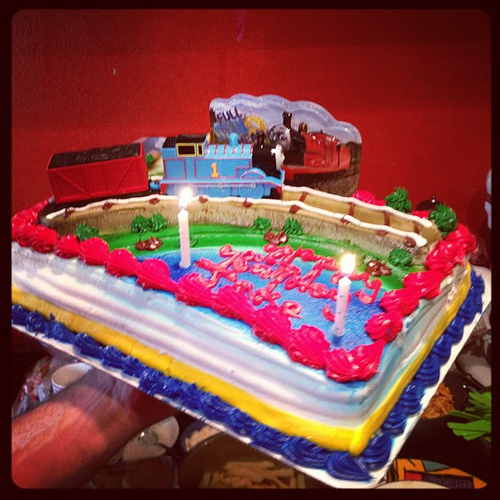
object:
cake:
[8, 90, 494, 489]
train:
[157, 130, 294, 205]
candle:
[174, 186, 199, 272]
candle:
[327, 251, 360, 341]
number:
[206, 158, 224, 183]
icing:
[0, 195, 499, 385]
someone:
[10, 367, 181, 490]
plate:
[368, 467, 496, 490]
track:
[41, 172, 442, 255]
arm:
[10, 379, 113, 490]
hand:
[89, 363, 187, 427]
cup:
[47, 360, 99, 397]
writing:
[189, 241, 384, 324]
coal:
[46, 141, 142, 172]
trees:
[386, 247, 415, 270]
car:
[41, 134, 152, 210]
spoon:
[136, 427, 186, 463]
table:
[10, 305, 497, 493]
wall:
[11, 8, 495, 353]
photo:
[1, 0, 500, 499]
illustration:
[201, 90, 370, 198]